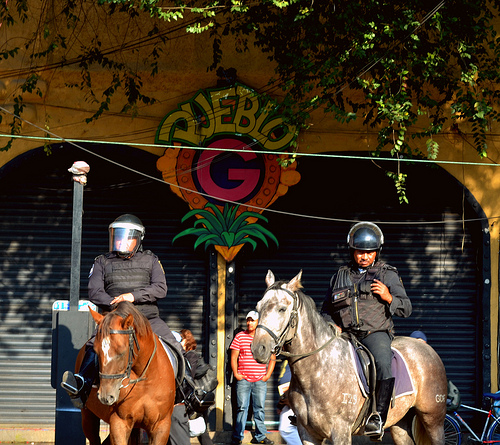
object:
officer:
[327, 217, 418, 438]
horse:
[251, 267, 454, 444]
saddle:
[353, 333, 400, 402]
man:
[225, 307, 277, 443]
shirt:
[231, 327, 274, 381]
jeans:
[237, 380, 266, 441]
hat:
[245, 309, 260, 321]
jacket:
[328, 261, 413, 334]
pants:
[345, 324, 395, 414]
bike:
[409, 387, 499, 445]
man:
[62, 206, 214, 400]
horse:
[68, 304, 193, 444]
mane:
[96, 298, 148, 327]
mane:
[290, 285, 332, 338]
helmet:
[108, 214, 145, 257]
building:
[3, 0, 500, 427]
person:
[180, 326, 218, 445]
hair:
[176, 327, 199, 354]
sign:
[158, 84, 303, 261]